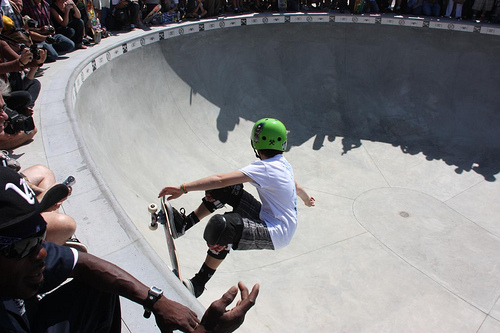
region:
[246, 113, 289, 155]
the man is wearing a helmet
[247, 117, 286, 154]
the helmet is made of plastic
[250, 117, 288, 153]
the plastic is green in color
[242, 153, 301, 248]
the man is wearing a t shirt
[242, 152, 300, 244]
the t shirt is white in color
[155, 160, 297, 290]
the man is holding the skateboard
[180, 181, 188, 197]
the man is wearing bracelets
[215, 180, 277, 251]
the man is wearing shorts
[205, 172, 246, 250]
the man is wearing knee pads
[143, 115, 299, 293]
the man is skateboarding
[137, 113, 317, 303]
A young boy skating in a skate bowl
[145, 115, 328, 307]
A young boy skateboarding in a skate bowl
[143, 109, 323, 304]
A young boy skateboarding in a skate bowl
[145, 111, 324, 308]
A young boy skateboarding in a skate bowl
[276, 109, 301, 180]
Green helmet on the boys head.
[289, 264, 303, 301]
Green helmet on the boys head.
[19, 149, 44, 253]
Green helmet on the boys head.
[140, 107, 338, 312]
person on a skateboard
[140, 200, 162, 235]
a pair of wheels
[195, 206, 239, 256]
black knee pad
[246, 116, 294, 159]
green helmet on the head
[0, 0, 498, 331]
people sitting around the ramp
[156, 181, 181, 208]
hand touching the board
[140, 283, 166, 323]
watch around the wrist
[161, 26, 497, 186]
shadows on the ramp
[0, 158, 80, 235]
black and white hat